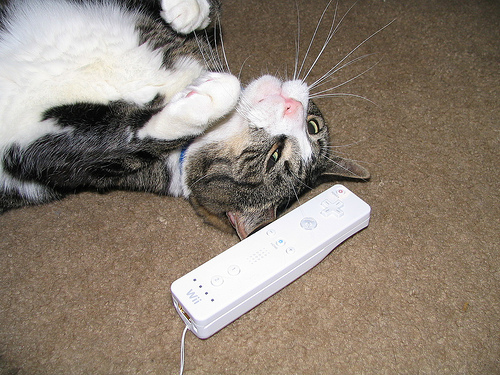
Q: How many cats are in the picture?
A: One.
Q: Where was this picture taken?
A: Living room.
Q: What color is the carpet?
A: Brown.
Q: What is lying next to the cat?
A: Wii controller.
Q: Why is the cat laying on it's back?
A: Resting.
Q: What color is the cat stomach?
A: White.